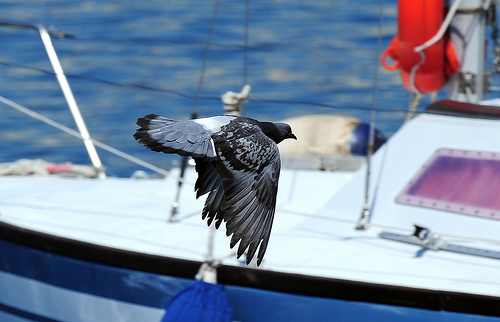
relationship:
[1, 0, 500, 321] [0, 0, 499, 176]
boat on water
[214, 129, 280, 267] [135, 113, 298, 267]
wing of bird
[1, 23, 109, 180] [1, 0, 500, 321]
metal on boat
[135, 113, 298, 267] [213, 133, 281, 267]
bird has wing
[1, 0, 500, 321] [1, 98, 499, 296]
boat has a deck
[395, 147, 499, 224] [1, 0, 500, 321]
window on boat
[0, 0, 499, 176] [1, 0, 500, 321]
water under boat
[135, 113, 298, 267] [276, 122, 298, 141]
bird has a head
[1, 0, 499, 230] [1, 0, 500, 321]
ropes on boat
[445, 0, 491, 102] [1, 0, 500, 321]
pole on boat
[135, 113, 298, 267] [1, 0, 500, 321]
bird above boat